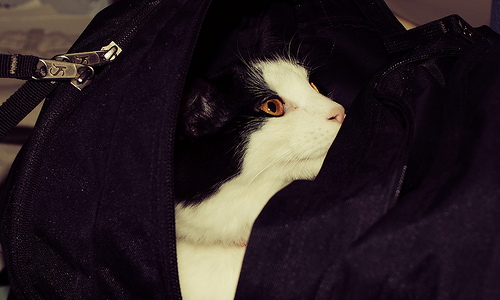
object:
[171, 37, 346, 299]
cat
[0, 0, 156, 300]
zipper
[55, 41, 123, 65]
pull tab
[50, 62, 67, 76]
logo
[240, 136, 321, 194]
whiskers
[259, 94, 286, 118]
eye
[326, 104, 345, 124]
nose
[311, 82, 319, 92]
eyes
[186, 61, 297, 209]
hair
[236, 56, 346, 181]
face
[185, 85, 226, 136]
ear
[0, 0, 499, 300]
backpack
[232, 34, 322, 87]
eyelashes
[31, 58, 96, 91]
tag